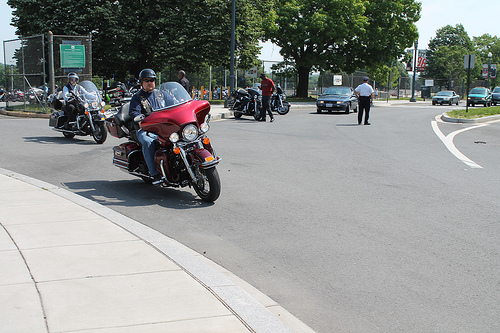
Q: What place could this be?
A: It is a street.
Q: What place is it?
A: It is a street.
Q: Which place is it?
A: It is a street.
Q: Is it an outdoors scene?
A: Yes, it is outdoors.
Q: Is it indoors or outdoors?
A: It is outdoors.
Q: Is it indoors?
A: No, it is outdoors.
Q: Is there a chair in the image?
A: No, there are no chairs.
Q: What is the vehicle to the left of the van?
A: The vehicle is a car.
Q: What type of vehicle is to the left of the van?
A: The vehicle is a car.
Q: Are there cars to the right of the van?
A: No, the car is to the left of the van.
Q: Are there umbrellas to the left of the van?
A: No, there is a car to the left of the van.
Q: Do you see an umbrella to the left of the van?
A: No, there is a car to the left of the van.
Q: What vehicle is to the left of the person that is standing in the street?
A: The vehicle is a car.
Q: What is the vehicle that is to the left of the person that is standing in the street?
A: The vehicle is a car.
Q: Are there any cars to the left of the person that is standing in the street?
A: Yes, there is a car to the left of the person.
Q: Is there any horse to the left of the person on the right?
A: No, there is a car to the left of the person.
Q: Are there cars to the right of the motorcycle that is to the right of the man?
A: Yes, there is a car to the right of the motorbike.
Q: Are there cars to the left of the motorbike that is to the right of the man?
A: No, the car is to the right of the motorcycle.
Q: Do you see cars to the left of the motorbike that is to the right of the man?
A: No, the car is to the right of the motorcycle.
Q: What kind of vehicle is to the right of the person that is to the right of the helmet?
A: The vehicle is a car.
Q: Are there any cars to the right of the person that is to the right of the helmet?
A: Yes, there is a car to the right of the person.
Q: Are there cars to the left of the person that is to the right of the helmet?
A: No, the car is to the right of the person.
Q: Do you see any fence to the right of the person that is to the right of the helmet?
A: No, there is a car to the right of the person.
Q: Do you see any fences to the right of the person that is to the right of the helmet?
A: No, there is a car to the right of the person.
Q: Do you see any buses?
A: No, there are no buses.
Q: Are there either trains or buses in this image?
A: No, there are no buses or trains.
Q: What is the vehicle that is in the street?
A: The vehicle is a car.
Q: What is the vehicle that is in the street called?
A: The vehicle is a car.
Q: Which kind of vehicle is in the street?
A: The vehicle is a car.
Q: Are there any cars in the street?
A: Yes, there is a car in the street.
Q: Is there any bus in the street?
A: No, there is a car in the street.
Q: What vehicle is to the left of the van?
A: The vehicle is a car.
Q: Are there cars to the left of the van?
A: Yes, there is a car to the left of the van.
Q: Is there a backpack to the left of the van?
A: No, there is a car to the left of the van.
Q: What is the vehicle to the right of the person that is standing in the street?
A: The vehicle is a car.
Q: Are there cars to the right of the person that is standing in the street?
A: Yes, there is a car to the right of the person.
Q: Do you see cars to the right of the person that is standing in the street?
A: Yes, there is a car to the right of the person.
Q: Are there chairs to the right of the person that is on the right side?
A: No, there is a car to the right of the person.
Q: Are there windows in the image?
A: Yes, there is a window.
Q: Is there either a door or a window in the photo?
A: Yes, there is a window.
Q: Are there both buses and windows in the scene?
A: No, there is a window but no buses.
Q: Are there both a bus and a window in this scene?
A: No, there is a window but no buses.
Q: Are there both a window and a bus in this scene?
A: No, there is a window but no buses.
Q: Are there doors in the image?
A: No, there are no doors.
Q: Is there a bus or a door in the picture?
A: No, there are no doors or buses.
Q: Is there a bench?
A: No, there are no benches.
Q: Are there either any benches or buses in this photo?
A: No, there are no benches or buses.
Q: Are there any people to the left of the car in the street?
A: Yes, there is a person to the left of the car.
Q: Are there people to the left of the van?
A: Yes, there is a person to the left of the van.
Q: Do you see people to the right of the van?
A: No, the person is to the left of the van.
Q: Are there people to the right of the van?
A: No, the person is to the left of the van.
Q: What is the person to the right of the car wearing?
A: The person is wearing a shirt.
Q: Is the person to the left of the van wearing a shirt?
A: Yes, the person is wearing a shirt.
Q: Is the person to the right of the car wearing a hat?
A: No, the person is wearing a shirt.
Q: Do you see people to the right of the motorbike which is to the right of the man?
A: Yes, there is a person to the right of the motorbike.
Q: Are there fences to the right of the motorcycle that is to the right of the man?
A: No, there is a person to the right of the motorbike.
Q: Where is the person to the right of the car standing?
A: The person is standing in the street.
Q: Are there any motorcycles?
A: Yes, there is a motorcycle.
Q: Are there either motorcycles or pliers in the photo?
A: Yes, there is a motorcycle.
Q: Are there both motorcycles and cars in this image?
A: Yes, there are both a motorcycle and a car.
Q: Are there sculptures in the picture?
A: No, there are no sculptures.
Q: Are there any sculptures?
A: No, there are no sculptures.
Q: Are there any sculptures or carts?
A: No, there are no sculptures or carts.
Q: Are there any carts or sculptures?
A: No, there are no sculptures or carts.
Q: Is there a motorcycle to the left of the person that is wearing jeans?
A: Yes, there is a motorcycle to the left of the person.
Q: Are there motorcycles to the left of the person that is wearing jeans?
A: Yes, there is a motorcycle to the left of the person.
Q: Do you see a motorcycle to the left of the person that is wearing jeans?
A: Yes, there is a motorcycle to the left of the person.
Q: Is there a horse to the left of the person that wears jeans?
A: No, there is a motorcycle to the left of the person.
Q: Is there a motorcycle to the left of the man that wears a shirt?
A: Yes, there is a motorcycle to the left of the man.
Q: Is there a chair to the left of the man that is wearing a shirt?
A: No, there is a motorcycle to the left of the man.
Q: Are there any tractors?
A: No, there are no tractors.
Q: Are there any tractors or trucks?
A: No, there are no tractors or trucks.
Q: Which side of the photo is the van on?
A: The van is on the right of the image.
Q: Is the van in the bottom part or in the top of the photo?
A: The van is in the top of the image.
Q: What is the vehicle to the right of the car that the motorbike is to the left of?
A: The vehicle is a van.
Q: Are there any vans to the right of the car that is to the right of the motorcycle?
A: Yes, there is a van to the right of the car.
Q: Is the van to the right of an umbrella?
A: No, the van is to the right of the car.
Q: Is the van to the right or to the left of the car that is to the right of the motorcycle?
A: The van is to the right of the car.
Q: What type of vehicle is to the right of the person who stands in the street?
A: The vehicle is a van.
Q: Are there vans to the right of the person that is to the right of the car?
A: Yes, there is a van to the right of the person.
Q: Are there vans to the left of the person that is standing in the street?
A: No, the van is to the right of the person.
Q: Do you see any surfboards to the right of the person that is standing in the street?
A: No, there is a van to the right of the person.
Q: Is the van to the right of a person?
A: Yes, the van is to the right of a person.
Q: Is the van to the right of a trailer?
A: No, the van is to the right of a person.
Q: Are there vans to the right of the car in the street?
A: Yes, there is a van to the right of the car.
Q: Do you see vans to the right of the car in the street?
A: Yes, there is a van to the right of the car.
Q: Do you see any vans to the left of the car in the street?
A: No, the van is to the right of the car.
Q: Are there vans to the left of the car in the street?
A: No, the van is to the right of the car.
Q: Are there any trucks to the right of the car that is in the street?
A: No, there is a van to the right of the car.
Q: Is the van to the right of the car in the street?
A: Yes, the van is to the right of the car.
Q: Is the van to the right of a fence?
A: No, the van is to the right of the car.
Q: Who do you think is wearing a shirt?
A: The man is wearing a shirt.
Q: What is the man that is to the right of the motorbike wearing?
A: The man is wearing a shirt.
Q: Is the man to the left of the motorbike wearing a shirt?
A: Yes, the man is wearing a shirt.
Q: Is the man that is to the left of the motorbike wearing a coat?
A: No, the man is wearing a shirt.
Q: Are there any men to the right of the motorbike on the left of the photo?
A: Yes, there is a man to the right of the motorcycle.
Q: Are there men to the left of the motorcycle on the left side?
A: No, the man is to the right of the motorbike.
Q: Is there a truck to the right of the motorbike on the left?
A: No, there is a man to the right of the motorcycle.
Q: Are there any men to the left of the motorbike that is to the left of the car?
A: Yes, there is a man to the left of the motorcycle.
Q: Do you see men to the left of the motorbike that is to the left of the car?
A: Yes, there is a man to the left of the motorcycle.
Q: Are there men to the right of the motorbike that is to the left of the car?
A: No, the man is to the left of the motorbike.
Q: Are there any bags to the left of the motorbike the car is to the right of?
A: No, there is a man to the left of the motorbike.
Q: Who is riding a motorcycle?
A: The man is riding a motorcycle.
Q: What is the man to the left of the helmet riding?
A: The man is riding a motorcycle.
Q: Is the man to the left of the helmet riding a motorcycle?
A: Yes, the man is riding a motorcycle.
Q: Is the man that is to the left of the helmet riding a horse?
A: No, the man is riding a motorcycle.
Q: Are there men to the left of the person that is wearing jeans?
A: Yes, there is a man to the left of the person.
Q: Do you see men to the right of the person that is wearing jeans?
A: No, the man is to the left of the person.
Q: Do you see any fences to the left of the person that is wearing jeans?
A: No, there is a man to the left of the person.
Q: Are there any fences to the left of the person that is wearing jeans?
A: No, there is a man to the left of the person.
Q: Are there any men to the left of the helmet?
A: Yes, there is a man to the left of the helmet.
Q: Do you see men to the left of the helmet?
A: Yes, there is a man to the left of the helmet.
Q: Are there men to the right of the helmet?
A: No, the man is to the left of the helmet.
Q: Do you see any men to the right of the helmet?
A: No, the man is to the left of the helmet.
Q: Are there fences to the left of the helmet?
A: No, there is a man to the left of the helmet.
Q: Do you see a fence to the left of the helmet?
A: No, there is a man to the left of the helmet.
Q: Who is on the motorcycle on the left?
A: The man is on the motorcycle.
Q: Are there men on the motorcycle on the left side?
A: Yes, there is a man on the motorbike.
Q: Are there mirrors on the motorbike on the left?
A: No, there is a man on the motorcycle.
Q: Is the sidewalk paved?
A: Yes, the sidewalk is paved.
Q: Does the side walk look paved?
A: Yes, the side walk is paved.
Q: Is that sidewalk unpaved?
A: No, the sidewalk is paved.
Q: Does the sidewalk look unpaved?
A: No, the sidewalk is paved.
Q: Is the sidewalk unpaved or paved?
A: The sidewalk is paved.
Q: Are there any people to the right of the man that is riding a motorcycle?
A: Yes, there is a person to the right of the man.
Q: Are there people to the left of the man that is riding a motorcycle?
A: No, the person is to the right of the man.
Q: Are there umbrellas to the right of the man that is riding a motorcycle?
A: No, there is a person to the right of the man.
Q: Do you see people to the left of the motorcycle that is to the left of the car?
A: Yes, there is a person to the left of the motorcycle.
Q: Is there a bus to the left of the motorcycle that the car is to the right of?
A: No, there is a person to the left of the motorcycle.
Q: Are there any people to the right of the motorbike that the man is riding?
A: Yes, there is a person to the right of the motorcycle.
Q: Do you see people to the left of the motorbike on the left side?
A: No, the person is to the right of the motorbike.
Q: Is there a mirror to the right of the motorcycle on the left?
A: No, there is a person to the right of the motorbike.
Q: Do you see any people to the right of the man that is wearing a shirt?
A: Yes, there is a person to the right of the man.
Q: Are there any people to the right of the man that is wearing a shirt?
A: Yes, there is a person to the right of the man.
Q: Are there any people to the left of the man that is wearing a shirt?
A: No, the person is to the right of the man.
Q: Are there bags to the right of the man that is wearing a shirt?
A: No, there is a person to the right of the man.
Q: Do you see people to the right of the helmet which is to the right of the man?
A: Yes, there is a person to the right of the helmet.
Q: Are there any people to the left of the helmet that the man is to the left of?
A: No, the person is to the right of the helmet.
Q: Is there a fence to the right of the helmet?
A: No, there is a person to the right of the helmet.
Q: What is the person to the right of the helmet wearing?
A: The person is wearing a shirt.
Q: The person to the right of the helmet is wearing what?
A: The person is wearing a shirt.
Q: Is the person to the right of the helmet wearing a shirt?
A: Yes, the person is wearing a shirt.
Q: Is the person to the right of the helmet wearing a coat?
A: No, the person is wearing a shirt.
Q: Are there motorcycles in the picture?
A: Yes, there is a motorcycle.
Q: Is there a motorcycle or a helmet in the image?
A: Yes, there is a motorcycle.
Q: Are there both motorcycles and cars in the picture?
A: Yes, there are both a motorcycle and a car.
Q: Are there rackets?
A: No, there are no rackets.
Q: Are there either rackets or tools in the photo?
A: No, there are no rackets or tools.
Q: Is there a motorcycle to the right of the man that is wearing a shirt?
A: Yes, there is a motorcycle to the right of the man.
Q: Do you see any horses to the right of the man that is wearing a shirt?
A: No, there is a motorcycle to the right of the man.